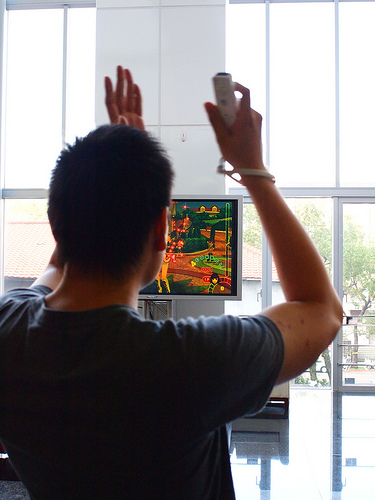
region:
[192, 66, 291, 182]
A Wii remote.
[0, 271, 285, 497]
He is wearing a black shirt.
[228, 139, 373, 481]
A lot of natural light in the picture.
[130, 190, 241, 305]
A tv in front of the person.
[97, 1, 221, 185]
The wall is white.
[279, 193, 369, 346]
Trees are outside the window.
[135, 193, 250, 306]
A game is on the tv.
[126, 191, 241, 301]
The tv is on.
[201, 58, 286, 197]
The remote is white.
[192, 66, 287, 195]
The remote has a lanyard.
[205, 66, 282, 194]
white wii remote and strap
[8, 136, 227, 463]
man wearing black tshirt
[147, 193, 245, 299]
flat screen tv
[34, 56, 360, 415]
man with both hands in air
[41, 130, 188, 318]
back of a man's head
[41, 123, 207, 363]
man with short black hair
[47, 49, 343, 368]
man holding a wii remote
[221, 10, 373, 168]
large windows with white frame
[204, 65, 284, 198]
hand holding a remote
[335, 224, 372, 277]
tree with green leaves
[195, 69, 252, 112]
white wii remote in hand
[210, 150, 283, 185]
white cord for remote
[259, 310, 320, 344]
small spots on man's arm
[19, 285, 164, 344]
collar on man's shirt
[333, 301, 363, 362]
silver handle on door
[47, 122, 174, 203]
man's spiky black hair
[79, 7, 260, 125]
white sheet on window panes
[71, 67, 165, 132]
mans fingers pointing up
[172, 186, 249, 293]
white edge of screen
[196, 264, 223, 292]
girl's head in screen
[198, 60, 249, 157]
Wii system hand controler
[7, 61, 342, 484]
Asian man playing Wii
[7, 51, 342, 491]
boy playing Wii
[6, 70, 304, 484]
boy in a blue t-shirt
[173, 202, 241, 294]
video game on a television set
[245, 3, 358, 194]
windows with the sun shining in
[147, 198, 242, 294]
large flat screen TV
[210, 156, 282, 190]
cream colored paracord bracelet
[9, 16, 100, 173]
modern paned windows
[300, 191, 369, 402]
glass and metal doors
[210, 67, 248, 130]
a white game controller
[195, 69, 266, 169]
the hand of a person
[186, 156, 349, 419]
the arm of a person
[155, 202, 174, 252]
the ear of a person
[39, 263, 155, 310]
the neck of a person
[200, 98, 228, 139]
the thumb of a person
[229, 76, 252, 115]
the finger of a person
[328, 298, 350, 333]
the elbow of a person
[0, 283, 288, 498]
a gray tee shirt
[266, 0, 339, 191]
the window of the building